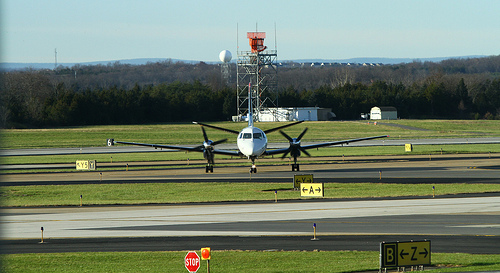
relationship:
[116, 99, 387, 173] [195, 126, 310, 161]
plane has propellers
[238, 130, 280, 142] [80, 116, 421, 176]
windshield for plane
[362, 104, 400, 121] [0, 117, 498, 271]
barn in field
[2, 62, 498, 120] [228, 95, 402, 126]
trees behind buildings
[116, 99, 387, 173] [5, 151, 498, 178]
plane on taxi way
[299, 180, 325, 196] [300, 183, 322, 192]
sign with arrows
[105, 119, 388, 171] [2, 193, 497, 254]
plane on runway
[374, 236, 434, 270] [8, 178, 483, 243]
sign on runway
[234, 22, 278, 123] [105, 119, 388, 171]
communication tower behind plane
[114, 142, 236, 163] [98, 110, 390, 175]
wing on plane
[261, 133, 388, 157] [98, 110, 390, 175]
wings on plane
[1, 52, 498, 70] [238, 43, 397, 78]
mountains behind area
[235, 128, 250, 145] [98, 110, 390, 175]
window on plane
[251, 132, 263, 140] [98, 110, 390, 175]
windshield on plane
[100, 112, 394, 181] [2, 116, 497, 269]
plane under runway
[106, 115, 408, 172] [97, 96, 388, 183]
wings on plane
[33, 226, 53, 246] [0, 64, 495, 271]
runway marker on airport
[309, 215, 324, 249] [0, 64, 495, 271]
runway marker on airport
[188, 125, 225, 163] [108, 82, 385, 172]
propeller on plane